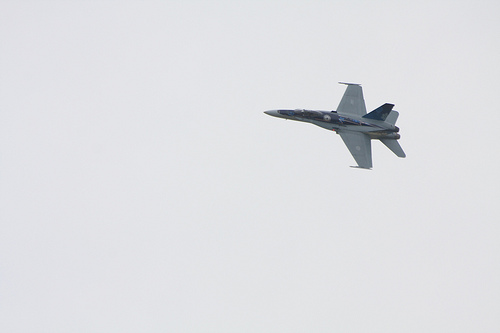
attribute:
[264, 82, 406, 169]
plane — white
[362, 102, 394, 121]
tail fin — blue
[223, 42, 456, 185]
jet — fighter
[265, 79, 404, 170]
aircraft — silver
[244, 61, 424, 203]
aircraft — white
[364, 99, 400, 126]
tail — black 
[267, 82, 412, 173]
aircraft — silver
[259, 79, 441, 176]
aircraft — silver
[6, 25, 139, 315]
sky — clear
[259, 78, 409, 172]
aircraft — silver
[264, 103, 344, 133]
back — black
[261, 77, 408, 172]
plane — moving , bent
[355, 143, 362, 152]
design — small